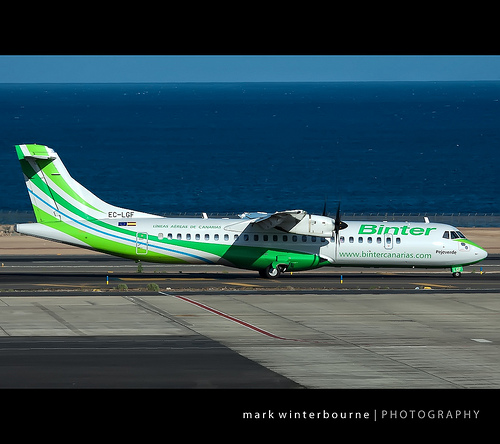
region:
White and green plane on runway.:
[4, 131, 499, 301]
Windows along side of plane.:
[160, 230, 318, 247]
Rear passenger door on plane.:
[131, 228, 151, 258]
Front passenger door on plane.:
[377, 225, 399, 250]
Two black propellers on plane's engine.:
[321, 200, 353, 246]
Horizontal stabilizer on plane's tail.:
[18, 149, 58, 171]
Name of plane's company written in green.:
[356, 218, 436, 244]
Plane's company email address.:
[333, 246, 437, 262]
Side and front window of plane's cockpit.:
[442, 223, 467, 246]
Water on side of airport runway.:
[344, 116, 499, 221]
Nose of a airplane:
[443, 234, 492, 279]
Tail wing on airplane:
[5, 125, 77, 237]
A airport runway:
[18, 280, 489, 397]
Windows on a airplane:
[154, 222, 399, 256]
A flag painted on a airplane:
[116, 220, 143, 229]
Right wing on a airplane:
[228, 204, 324, 246]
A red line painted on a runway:
[176, 291, 306, 363]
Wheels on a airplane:
[238, 255, 304, 284]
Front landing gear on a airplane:
[436, 260, 474, 287]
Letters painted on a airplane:
[346, 220, 446, 240]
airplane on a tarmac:
[11, 142, 488, 274]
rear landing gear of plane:
[256, 263, 290, 280]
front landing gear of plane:
[450, 264, 469, 279]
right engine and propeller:
[258, 205, 346, 239]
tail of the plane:
[11, 144, 95, 258]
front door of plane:
[383, 231, 395, 251]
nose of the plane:
[434, 222, 487, 269]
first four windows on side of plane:
[363, 233, 403, 245]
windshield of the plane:
[442, 226, 470, 243]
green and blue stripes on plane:
[15, 142, 322, 282]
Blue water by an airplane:
[110, 129, 316, 250]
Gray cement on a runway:
[285, 319, 435, 401]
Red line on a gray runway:
[156, 289, 281, 351]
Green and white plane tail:
[7, 138, 119, 256]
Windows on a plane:
[137, 225, 404, 248]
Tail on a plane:
[14, 144, 99, 213]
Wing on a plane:
[242, 208, 317, 239]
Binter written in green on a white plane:
[307, 191, 491, 268]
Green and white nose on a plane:
[420, 221, 490, 276]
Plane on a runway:
[20, 109, 465, 297]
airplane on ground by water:
[15, 110, 485, 355]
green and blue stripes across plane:
[20, 140, 255, 276]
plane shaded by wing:
[211, 200, 336, 285]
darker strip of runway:
[40, 240, 490, 300]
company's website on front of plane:
[330, 245, 436, 265]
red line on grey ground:
[150, 277, 310, 367]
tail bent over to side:
[10, 127, 65, 177]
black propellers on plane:
[302, 190, 353, 250]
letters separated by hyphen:
[96, 200, 146, 215]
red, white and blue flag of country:
[100, 217, 142, 228]